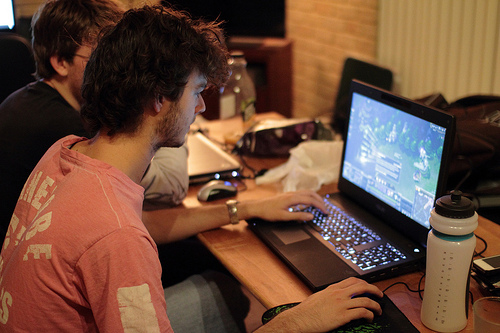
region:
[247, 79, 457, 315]
A black laptop computer.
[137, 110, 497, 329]
A brown wooden table.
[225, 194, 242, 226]
A wrist watch.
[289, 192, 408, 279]
A lit up keyboard on a laptop.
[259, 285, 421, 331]
A black mousepad.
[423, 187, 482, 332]
A white waterbottle with a black top.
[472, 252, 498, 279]
A smartphone.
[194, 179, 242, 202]
A silver and black computer mouse.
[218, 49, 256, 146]
A clear container with a black lid.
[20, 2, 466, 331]
A man on a laptop.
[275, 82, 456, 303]
laptop on the desk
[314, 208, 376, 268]
keyboard on the laptop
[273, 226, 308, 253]
track pad on laptop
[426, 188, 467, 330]
water bottle on desk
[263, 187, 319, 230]
hand of the man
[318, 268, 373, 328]
hand of the man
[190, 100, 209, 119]
nose of the man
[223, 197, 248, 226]
watch on the wrist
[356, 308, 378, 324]
finger of the man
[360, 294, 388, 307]
finger of the man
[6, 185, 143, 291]
red shirt with white letters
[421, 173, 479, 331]
a white bottle on a table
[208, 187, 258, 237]
a man wearing a watch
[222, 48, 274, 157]
an empty jug on a table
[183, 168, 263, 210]
a computer mouse on a table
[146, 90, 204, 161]
a man with facial hair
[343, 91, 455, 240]
a computer screen on a computer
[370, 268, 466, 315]
a black cord attached to a mouse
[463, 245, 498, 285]
a phone laying on a table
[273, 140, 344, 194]
paper laying on a table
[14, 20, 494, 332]
man using the laptop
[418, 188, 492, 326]
white water bottle with black top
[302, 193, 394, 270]
lit up keyboard on laptop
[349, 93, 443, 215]
screen of black laptop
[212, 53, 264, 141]
empty plastic bottle sitting on desk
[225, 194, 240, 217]
watch on wrist of man using laptop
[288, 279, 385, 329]
man's hand on mouse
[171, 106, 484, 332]
desk laptop is sitting on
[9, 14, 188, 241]
man wearing black shirt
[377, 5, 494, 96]
closed white blinds over window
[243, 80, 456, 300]
an open laptop computer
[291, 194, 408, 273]
a backlit computer keyboard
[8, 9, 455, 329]
a man using a computer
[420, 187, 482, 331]
a white water bottle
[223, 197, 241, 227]
a men's silver watch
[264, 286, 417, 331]
a black mouse pad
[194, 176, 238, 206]
a black and silver mouse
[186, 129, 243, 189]
a closed laptop computer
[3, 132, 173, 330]
a pink t-shirt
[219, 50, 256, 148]
a clear plastic bottle